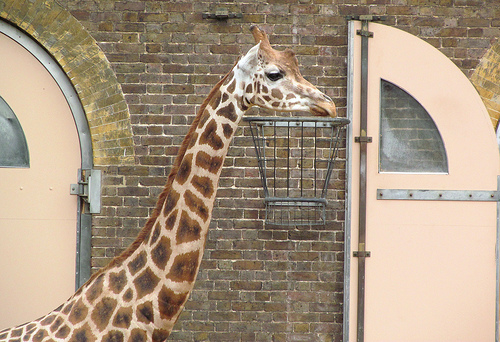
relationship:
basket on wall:
[243, 112, 349, 226] [104, 16, 184, 102]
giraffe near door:
[182, 37, 340, 179] [347, 17, 498, 340]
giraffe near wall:
[182, 37, 340, 179] [104, 16, 184, 102]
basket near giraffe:
[243, 112, 349, 226] [182, 37, 340, 179]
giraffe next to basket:
[182, 37, 340, 179] [243, 112, 349, 226]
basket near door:
[243, 112, 349, 226] [347, 17, 498, 340]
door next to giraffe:
[347, 17, 498, 340] [182, 37, 340, 179]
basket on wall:
[243, 112, 349, 226] [0, 0, 500, 340]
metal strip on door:
[376, 185, 498, 204] [347, 17, 498, 340]